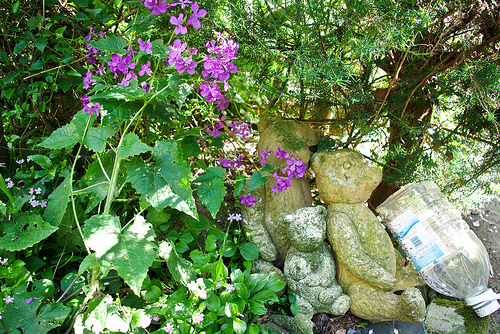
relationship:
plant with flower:
[1, 1, 304, 333] [188, 2, 206, 29]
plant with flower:
[1, 1, 304, 333] [171, 14, 189, 35]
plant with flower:
[1, 1, 304, 333] [145, 0, 166, 14]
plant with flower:
[1, 1, 304, 333] [171, 40, 188, 56]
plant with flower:
[1, 1, 304, 333] [202, 60, 225, 79]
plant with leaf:
[1, 1, 304, 333] [85, 214, 160, 296]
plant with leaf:
[1, 1, 304, 333] [0, 211, 58, 252]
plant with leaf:
[1, 1, 304, 333] [41, 173, 70, 228]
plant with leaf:
[1, 1, 304, 333] [125, 141, 199, 219]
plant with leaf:
[1, 1, 304, 333] [0, 292, 71, 333]